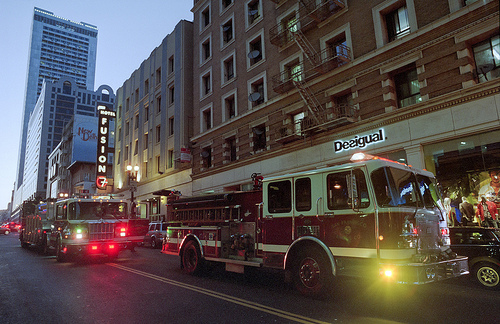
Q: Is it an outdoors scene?
A: Yes, it is outdoors.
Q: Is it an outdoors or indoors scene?
A: It is outdoors.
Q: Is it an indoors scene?
A: No, it is outdoors.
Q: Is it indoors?
A: No, it is outdoors.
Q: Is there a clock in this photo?
A: No, there are no clocks.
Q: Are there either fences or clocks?
A: No, there are no clocks or fences.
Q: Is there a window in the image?
A: Yes, there is a window.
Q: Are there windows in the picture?
A: Yes, there is a window.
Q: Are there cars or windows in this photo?
A: Yes, there is a window.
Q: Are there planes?
A: No, there are no planes.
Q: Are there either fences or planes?
A: No, there are no planes or fences.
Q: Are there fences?
A: No, there are no fences.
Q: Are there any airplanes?
A: No, there are no airplanes.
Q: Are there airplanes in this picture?
A: No, there are no airplanes.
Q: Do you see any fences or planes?
A: No, there are no planes or fences.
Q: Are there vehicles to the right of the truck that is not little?
A: Yes, there is a vehicle to the right of the truck.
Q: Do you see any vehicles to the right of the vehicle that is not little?
A: Yes, there is a vehicle to the right of the truck.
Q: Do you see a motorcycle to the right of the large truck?
A: No, there is a vehicle to the right of the truck.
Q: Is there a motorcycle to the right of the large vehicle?
A: No, there is a vehicle to the right of the truck.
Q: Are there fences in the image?
A: No, there are no fences.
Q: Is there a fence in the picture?
A: No, there are no fences.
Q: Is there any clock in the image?
A: No, there are no clocks.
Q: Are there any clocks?
A: No, there are no clocks.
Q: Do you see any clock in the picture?
A: No, there are no clocks.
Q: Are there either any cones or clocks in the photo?
A: No, there are no clocks or cones.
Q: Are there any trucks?
A: Yes, there is a truck.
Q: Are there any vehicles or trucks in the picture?
A: Yes, there is a truck.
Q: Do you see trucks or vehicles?
A: Yes, there is a truck.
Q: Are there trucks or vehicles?
A: Yes, there is a truck.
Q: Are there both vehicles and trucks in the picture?
A: Yes, there are both a truck and vehicles.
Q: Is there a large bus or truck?
A: Yes, there is a large truck.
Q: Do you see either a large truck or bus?
A: Yes, there is a large truck.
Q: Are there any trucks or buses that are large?
A: Yes, the truck is large.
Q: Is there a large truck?
A: Yes, there is a large truck.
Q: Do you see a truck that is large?
A: Yes, there is a truck that is large.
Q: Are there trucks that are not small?
A: Yes, there is a large truck.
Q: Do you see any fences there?
A: No, there are no fences.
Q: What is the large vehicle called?
A: The vehicle is a truck.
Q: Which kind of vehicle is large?
A: The vehicle is a truck.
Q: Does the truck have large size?
A: Yes, the truck is large.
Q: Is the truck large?
A: Yes, the truck is large.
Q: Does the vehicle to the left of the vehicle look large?
A: Yes, the truck is large.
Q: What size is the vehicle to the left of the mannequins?
A: The truck is large.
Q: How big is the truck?
A: The truck is large.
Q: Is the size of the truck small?
A: No, the truck is large.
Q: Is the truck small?
A: No, the truck is large.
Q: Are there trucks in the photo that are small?
A: No, there is a truck but it is large.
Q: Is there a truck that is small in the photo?
A: No, there is a truck but it is large.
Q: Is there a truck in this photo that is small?
A: No, there is a truck but it is large.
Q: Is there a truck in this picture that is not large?
A: No, there is a truck but it is large.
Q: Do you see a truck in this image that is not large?
A: No, there is a truck but it is large.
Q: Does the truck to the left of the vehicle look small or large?
A: The truck is large.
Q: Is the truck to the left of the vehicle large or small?
A: The truck is large.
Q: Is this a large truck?
A: Yes, this is a large truck.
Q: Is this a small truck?
A: No, this is a large truck.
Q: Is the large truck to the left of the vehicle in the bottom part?
A: Yes, the truck is to the left of the vehicle.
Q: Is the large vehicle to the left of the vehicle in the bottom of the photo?
A: Yes, the truck is to the left of the vehicle.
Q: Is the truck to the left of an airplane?
A: No, the truck is to the left of the vehicle.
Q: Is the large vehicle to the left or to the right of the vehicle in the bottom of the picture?
A: The truck is to the left of the vehicle.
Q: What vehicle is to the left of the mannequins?
A: The vehicle is a truck.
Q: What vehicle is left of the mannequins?
A: The vehicle is a truck.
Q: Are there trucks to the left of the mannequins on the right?
A: Yes, there is a truck to the left of the mannequins.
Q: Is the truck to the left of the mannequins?
A: Yes, the truck is to the left of the mannequins.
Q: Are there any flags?
A: No, there are no flags.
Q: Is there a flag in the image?
A: No, there are no flags.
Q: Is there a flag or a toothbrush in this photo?
A: No, there are no flags or toothbrushes.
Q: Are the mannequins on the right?
A: Yes, the mannequins are on the right of the image.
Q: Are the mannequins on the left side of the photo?
A: No, the mannequins are on the right of the image.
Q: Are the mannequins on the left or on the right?
A: The mannequins are on the right of the image.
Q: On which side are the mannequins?
A: The mannequins are on the right of the image.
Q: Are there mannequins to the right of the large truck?
A: Yes, there are mannequins to the right of the truck.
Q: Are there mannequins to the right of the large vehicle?
A: Yes, there are mannequins to the right of the truck.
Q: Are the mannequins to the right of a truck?
A: Yes, the mannequins are to the right of a truck.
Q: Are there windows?
A: Yes, there are windows.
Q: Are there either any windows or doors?
A: Yes, there are windows.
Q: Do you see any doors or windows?
A: Yes, there are windows.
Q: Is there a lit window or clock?
A: Yes, there are lit windows.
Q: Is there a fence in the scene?
A: No, there are no fences.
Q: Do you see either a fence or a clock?
A: No, there are no clocks or fences.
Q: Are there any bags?
A: No, there are no bags.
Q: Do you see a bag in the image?
A: No, there are no bags.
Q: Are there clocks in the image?
A: No, there are no clocks.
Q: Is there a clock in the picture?
A: No, there are no clocks.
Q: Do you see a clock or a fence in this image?
A: No, there are no clocks or fences.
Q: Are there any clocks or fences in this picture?
A: No, there are no clocks or fences.